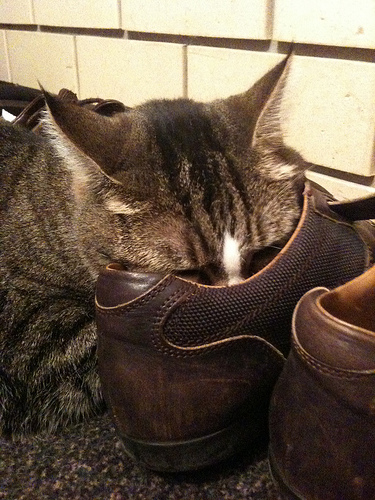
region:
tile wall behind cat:
[0, 1, 372, 199]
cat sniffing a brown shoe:
[95, 186, 374, 472]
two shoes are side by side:
[92, 177, 374, 498]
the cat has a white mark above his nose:
[220, 231, 244, 284]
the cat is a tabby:
[0, 43, 373, 423]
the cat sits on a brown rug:
[0, 411, 303, 497]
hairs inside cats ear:
[38, 108, 125, 202]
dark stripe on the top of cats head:
[143, 99, 232, 170]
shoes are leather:
[91, 178, 373, 497]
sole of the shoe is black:
[117, 418, 292, 472]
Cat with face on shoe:
[3, 50, 308, 443]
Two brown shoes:
[84, 172, 373, 489]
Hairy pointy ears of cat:
[33, 49, 309, 194]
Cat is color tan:
[5, 52, 321, 453]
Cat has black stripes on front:
[147, 112, 262, 258]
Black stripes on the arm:
[5, 296, 103, 407]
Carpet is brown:
[7, 409, 305, 499]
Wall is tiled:
[0, 8, 373, 229]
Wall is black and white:
[4, 7, 373, 241]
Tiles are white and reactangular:
[0, 8, 373, 171]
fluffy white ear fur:
[35, 107, 82, 174]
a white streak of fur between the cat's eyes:
[220, 227, 246, 287]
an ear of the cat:
[223, 41, 299, 152]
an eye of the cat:
[250, 234, 285, 266]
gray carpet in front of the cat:
[0, 411, 288, 498]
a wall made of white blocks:
[0, 0, 373, 207]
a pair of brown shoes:
[89, 177, 374, 498]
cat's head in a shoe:
[35, 39, 309, 290]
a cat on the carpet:
[0, 40, 324, 441]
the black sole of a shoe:
[114, 422, 238, 474]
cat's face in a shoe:
[75, 111, 289, 331]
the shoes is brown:
[119, 265, 363, 498]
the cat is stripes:
[48, 82, 305, 335]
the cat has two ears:
[21, 65, 299, 239]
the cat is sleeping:
[49, 107, 316, 340]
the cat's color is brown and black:
[9, 144, 129, 405]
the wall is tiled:
[47, 16, 198, 92]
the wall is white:
[52, 10, 275, 88]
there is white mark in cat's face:
[190, 200, 257, 279]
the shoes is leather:
[105, 249, 373, 445]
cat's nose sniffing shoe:
[212, 227, 245, 294]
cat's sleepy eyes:
[161, 238, 287, 281]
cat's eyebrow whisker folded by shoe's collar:
[259, 240, 287, 257]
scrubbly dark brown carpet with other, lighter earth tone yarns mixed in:
[0, 408, 288, 498]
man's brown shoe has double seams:
[142, 279, 285, 368]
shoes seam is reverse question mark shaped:
[142, 281, 285, 362]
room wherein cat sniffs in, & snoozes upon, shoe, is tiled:
[0, 0, 373, 207]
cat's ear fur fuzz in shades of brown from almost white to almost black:
[30, 76, 146, 211]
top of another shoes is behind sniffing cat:
[0, 82, 121, 122]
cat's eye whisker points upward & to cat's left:
[230, 158, 316, 245]